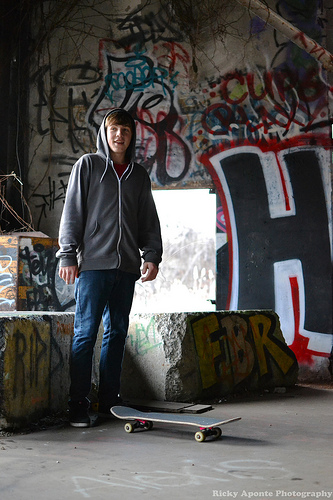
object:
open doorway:
[129, 185, 215, 315]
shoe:
[69, 413, 91, 428]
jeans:
[69, 270, 135, 412]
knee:
[70, 335, 96, 366]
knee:
[102, 325, 127, 353]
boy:
[56, 106, 164, 429]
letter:
[195, 131, 332, 384]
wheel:
[124, 423, 132, 433]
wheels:
[212, 427, 222, 437]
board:
[109, 405, 243, 442]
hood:
[101, 108, 133, 154]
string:
[99, 154, 108, 184]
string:
[125, 161, 134, 181]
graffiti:
[0, 0, 333, 433]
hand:
[141, 262, 159, 284]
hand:
[59, 266, 79, 285]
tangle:
[0, 171, 36, 233]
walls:
[0, 0, 333, 433]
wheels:
[144, 421, 154, 430]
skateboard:
[110, 406, 242, 444]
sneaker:
[95, 403, 117, 421]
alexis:
[0, 382, 333, 499]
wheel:
[194, 431, 203, 442]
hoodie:
[56, 107, 163, 272]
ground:
[0, 381, 333, 500]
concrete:
[0, 0, 333, 424]